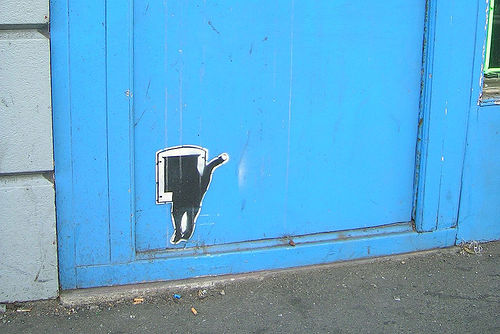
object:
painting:
[149, 141, 234, 250]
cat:
[163, 150, 232, 247]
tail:
[201, 152, 230, 192]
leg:
[182, 206, 207, 240]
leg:
[169, 201, 184, 244]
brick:
[0, 0, 52, 34]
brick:
[0, 26, 57, 179]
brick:
[0, 173, 65, 308]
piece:
[172, 292, 182, 299]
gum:
[172, 292, 183, 297]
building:
[0, 0, 495, 330]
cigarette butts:
[125, 290, 153, 312]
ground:
[0, 257, 500, 334]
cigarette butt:
[190, 303, 197, 316]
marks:
[32, 267, 53, 284]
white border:
[153, 143, 208, 207]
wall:
[1, 7, 63, 309]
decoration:
[450, 236, 489, 261]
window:
[480, 2, 498, 98]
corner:
[471, 70, 496, 110]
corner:
[396, 188, 433, 239]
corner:
[126, 227, 153, 267]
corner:
[49, 274, 69, 308]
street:
[0, 246, 500, 333]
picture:
[154, 143, 228, 243]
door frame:
[114, 195, 426, 260]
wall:
[0, 3, 500, 305]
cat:
[168, 152, 228, 242]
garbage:
[437, 239, 499, 266]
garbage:
[124, 282, 233, 318]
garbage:
[0, 305, 92, 315]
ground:
[244, 256, 424, 334]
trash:
[189, 290, 214, 293]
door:
[38, 0, 483, 290]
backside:
[147, 143, 237, 244]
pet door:
[155, 145, 206, 208]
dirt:
[121, 216, 423, 263]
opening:
[149, 145, 222, 205]